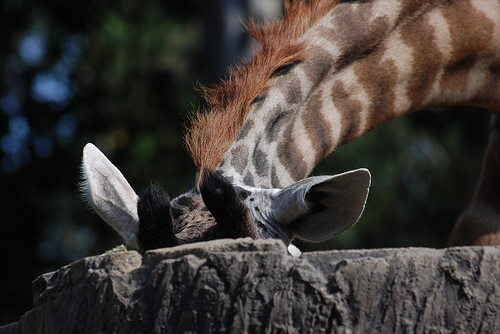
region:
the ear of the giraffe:
[270, 165, 370, 247]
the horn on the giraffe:
[197, 165, 259, 236]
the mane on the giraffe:
[180, 0, 343, 192]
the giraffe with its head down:
[78, 0, 498, 255]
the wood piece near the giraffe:
[0, 236, 497, 332]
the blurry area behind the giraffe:
[2, 0, 499, 265]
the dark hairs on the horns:
[138, 165, 259, 250]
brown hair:
[195, 109, 235, 148]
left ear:
[278, 154, 379, 234]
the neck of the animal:
[241, 121, 306, 172]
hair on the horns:
[136, 193, 181, 240]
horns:
[196, 168, 250, 231]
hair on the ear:
[77, 140, 133, 225]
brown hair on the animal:
[191, 116, 241, 152]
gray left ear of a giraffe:
[272, 165, 372, 243]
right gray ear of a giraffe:
[75, 138, 140, 248]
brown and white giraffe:
[74, 1, 498, 248]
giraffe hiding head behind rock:
[70, 1, 498, 243]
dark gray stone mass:
[2, 240, 497, 332]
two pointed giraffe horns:
[135, 163, 255, 244]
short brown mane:
[182, 1, 338, 168]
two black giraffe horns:
[132, 163, 256, 251]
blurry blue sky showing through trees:
[2, 23, 87, 168]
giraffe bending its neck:
[77, 2, 499, 249]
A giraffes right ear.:
[80, 143, 140, 250]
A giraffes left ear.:
[271, 165, 371, 242]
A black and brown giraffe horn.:
[202, 165, 259, 240]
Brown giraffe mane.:
[184, 0, 336, 179]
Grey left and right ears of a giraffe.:
[80, 142, 370, 245]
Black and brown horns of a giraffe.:
[137, 169, 260, 251]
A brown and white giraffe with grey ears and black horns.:
[80, 0, 499, 252]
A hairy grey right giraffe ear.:
[82, 144, 137, 246]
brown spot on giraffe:
[229, 142, 249, 171]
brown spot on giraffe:
[262, 98, 296, 141]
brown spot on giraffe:
[274, 114, 308, 182]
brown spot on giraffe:
[330, 78, 360, 148]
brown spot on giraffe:
[298, 42, 334, 83]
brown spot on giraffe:
[398, 1, 441, 107]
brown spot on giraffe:
[435, 1, 497, 97]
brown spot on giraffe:
[317, 0, 397, 131]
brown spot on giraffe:
[241, 166, 251, 182]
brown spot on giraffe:
[232, 117, 255, 137]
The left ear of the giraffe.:
[74, 146, 140, 244]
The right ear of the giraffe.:
[281, 166, 369, 245]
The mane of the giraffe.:
[180, 0, 322, 165]